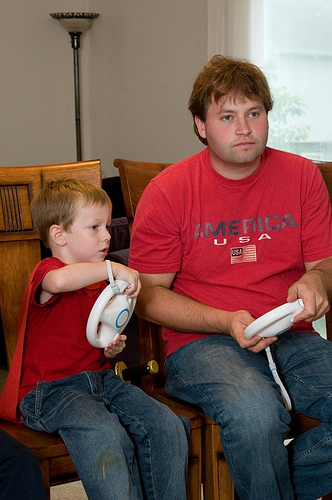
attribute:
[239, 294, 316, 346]
steering wheel —  plastic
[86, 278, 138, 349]
wheel — White , plastic steering 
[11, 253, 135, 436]
shirt —  red 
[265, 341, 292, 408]
wire — white, hanging down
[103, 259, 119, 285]
strap —  white 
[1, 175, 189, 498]
boy — playing game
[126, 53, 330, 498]
man — playing game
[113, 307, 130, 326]
circle —  blue 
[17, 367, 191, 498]
jeans — blue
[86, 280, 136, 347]
wii controller — white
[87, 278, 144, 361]
steering wheel — plastic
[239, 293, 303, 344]
steering wheel — plastic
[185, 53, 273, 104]
hair —  brown